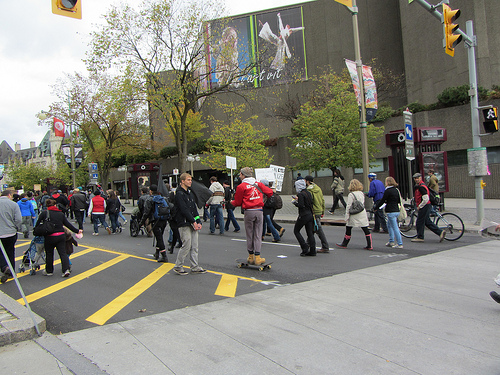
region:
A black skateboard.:
[236, 256, 273, 272]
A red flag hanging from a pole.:
[53, 116, 67, 137]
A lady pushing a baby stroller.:
[16, 197, 83, 278]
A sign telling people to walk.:
[481, 104, 499, 135]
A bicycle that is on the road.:
[396, 201, 464, 241]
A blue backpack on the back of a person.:
[153, 193, 173, 220]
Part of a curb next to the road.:
[0, 287, 47, 344]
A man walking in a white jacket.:
[206, 174, 226, 236]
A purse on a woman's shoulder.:
[349, 188, 364, 215]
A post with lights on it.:
[186, 153, 201, 180]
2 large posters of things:
[205, 4, 304, 84]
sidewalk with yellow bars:
[51, 233, 247, 340]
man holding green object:
[175, 181, 220, 251]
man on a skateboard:
[226, 163, 278, 267]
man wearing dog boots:
[243, 237, 275, 277]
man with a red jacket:
[236, 178, 288, 232]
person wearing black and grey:
[285, 178, 341, 252]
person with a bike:
[406, 165, 483, 252]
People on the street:
[0, 165, 448, 282]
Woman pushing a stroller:
[18, 198, 81, 280]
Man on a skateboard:
[228, 167, 273, 271]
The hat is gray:
[412, 172, 420, 179]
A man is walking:
[209, 177, 226, 234]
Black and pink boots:
[337, 232, 374, 251]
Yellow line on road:
[1, 241, 268, 325]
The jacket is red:
[227, 180, 273, 210]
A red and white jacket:
[88, 195, 106, 217]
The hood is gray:
[294, 179, 306, 192]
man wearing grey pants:
[245, 215, 250, 230]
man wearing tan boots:
[241, 250, 266, 261]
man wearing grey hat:
[238, 162, 253, 175]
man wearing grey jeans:
[182, 230, 190, 253]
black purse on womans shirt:
[32, 221, 55, 236]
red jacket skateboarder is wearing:
[229, 177, 273, 209]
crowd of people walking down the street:
[1, 172, 463, 278]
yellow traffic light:
[441, 3, 461, 55]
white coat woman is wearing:
[343, 190, 368, 225]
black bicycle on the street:
[392, 196, 463, 236]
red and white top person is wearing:
[87, 196, 105, 213]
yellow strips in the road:
[0, 235, 281, 326]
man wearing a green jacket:
[305, 180, 325, 215]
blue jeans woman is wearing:
[385, 211, 403, 243]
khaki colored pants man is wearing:
[178, 227, 201, 269]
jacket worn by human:
[172, 183, 200, 225]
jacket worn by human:
[226, 181, 274, 209]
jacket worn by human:
[0, 197, 26, 239]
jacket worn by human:
[85, 194, 107, 215]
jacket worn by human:
[136, 193, 172, 223]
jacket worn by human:
[207, 182, 224, 206]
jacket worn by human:
[305, 186, 327, 216]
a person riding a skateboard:
[229, 166, 276, 271]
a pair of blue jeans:
[385, 212, 401, 242]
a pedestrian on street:
[377, 175, 405, 245]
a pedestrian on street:
[340, 177, 373, 249]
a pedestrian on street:
[290, 178, 315, 253]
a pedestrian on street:
[260, 179, 281, 241]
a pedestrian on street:
[204, 175, 225, 231]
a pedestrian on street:
[221, 180, 239, 232]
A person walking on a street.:
[304, 175, 332, 253]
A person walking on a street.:
[341, 179, 373, 251]